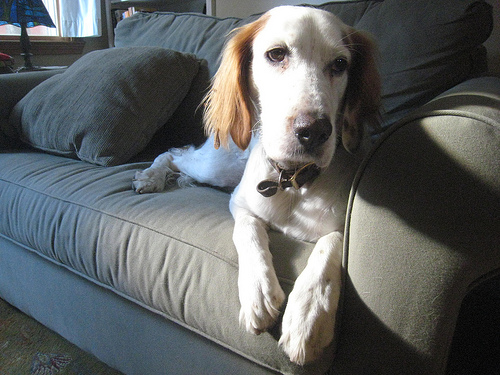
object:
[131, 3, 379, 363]
dog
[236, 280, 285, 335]
paws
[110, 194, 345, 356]
sun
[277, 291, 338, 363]
paw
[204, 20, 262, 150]
ear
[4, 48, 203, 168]
pillow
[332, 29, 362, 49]
whiskers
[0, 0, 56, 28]
cover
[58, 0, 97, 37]
curtain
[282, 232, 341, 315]
leg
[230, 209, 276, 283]
leg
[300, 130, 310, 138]
nostril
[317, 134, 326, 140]
nostril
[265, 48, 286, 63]
eye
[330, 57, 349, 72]
eye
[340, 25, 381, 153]
ear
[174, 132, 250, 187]
leg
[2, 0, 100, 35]
window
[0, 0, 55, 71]
lamp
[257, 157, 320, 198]
collar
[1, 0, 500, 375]
couch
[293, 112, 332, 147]
nose